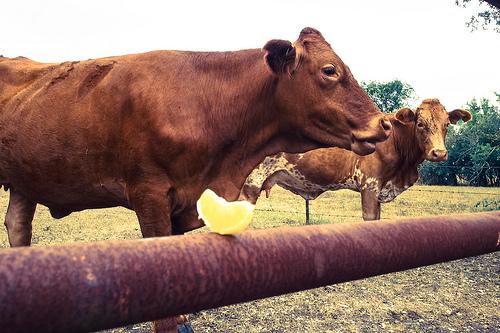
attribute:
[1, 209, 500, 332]
pole — rusty, metal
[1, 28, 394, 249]
cow — brown, standing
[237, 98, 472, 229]
cow — brown, white, standing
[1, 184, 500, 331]
grass — green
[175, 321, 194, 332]
hoof — black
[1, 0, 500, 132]
sky — bright